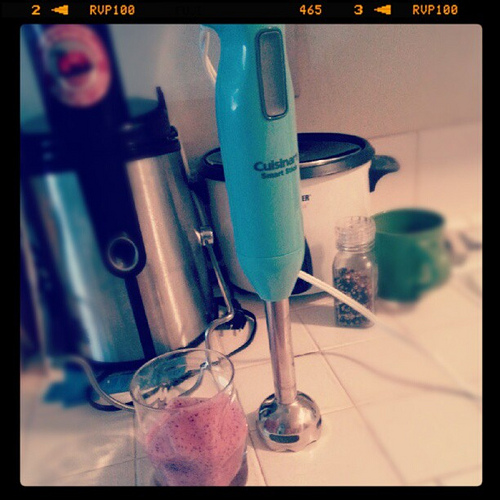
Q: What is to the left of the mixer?
A: Juicer.